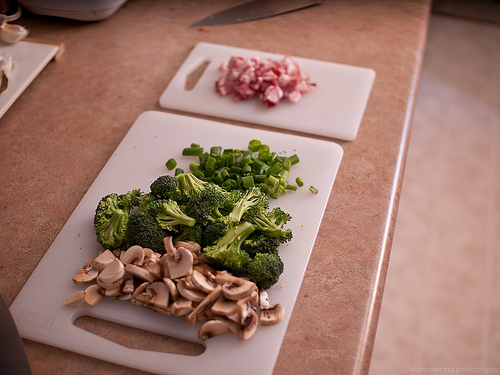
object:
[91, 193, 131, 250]
brocolli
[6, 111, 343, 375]
board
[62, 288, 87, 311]
mushrooms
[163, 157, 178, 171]
chives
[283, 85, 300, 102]
meat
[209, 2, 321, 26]
knife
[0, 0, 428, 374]
table